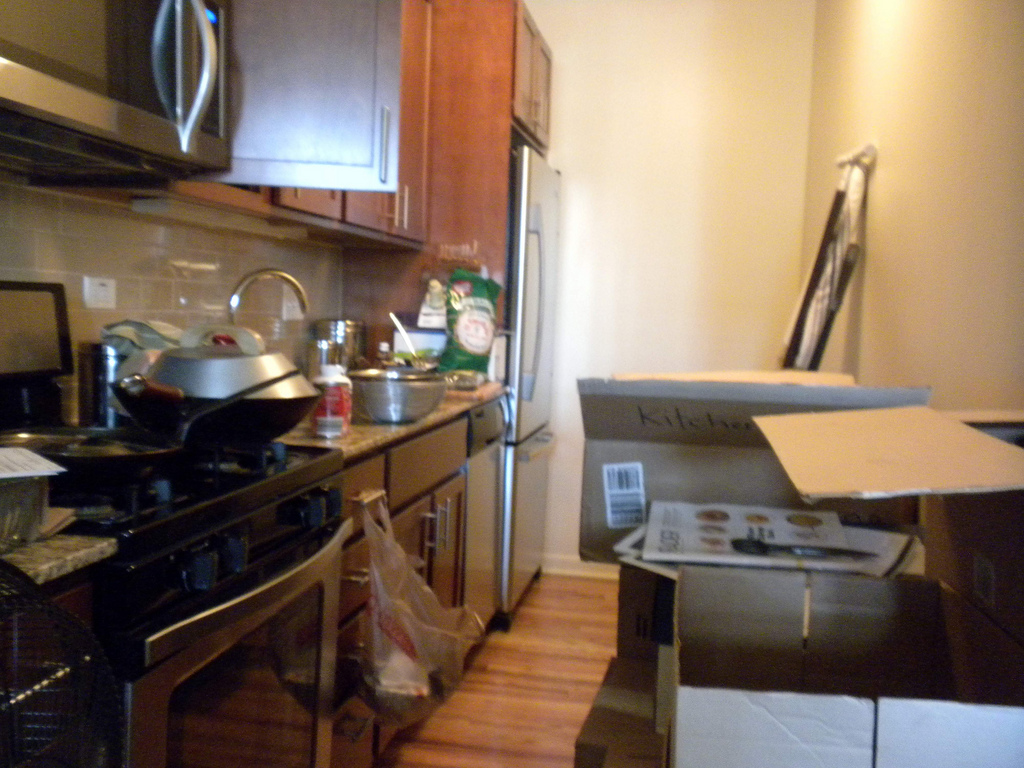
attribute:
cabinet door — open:
[197, 0, 412, 206]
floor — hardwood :
[497, 548, 665, 765]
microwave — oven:
[9, 0, 245, 203]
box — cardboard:
[573, 352, 932, 529]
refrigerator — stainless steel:
[472, 128, 562, 634]